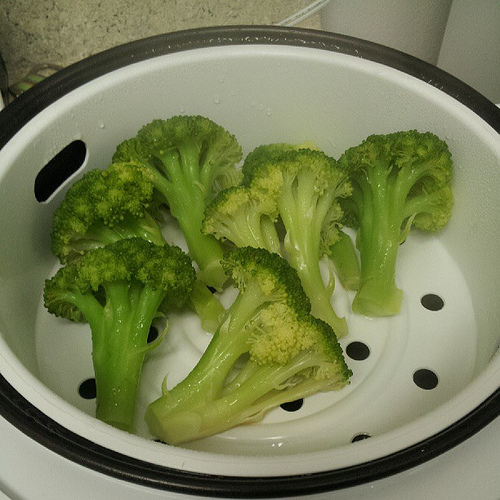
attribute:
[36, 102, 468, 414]
broccoli — wet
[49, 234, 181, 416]
broccoli — green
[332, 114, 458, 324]
broccoli — cooked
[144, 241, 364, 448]
broccoli — yellow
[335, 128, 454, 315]
broccoli — green, yellow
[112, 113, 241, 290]
broccoli — yellow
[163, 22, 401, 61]
rim — black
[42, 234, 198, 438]
broccoli — yellow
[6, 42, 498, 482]
bowl — steam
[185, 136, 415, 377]
broccoli — green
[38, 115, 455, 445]
broccoli — green, steam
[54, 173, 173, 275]
broccoli — green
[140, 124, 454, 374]
brocolli — green, steamed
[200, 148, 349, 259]
broccoli — yellow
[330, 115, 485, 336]
brocolli — steamed 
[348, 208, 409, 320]
stem — green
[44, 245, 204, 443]
broccoli — clean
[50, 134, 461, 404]
brocolli — steamed, green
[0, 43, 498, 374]
coating — wide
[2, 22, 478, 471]
bowl — steamed